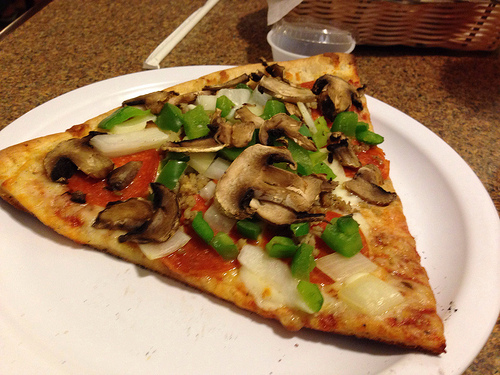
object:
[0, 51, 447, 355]
pizza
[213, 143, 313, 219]
mushrooms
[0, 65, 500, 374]
plate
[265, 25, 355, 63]
container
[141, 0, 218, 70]
straw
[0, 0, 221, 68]
table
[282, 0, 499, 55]
basket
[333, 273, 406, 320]
onion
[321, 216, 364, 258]
bell pepper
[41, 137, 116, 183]
pepperoni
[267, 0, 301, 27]
liner